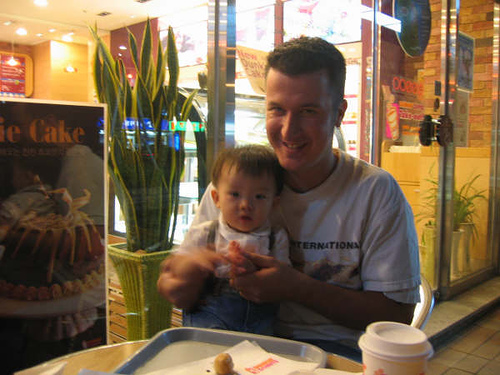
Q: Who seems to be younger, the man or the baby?
A: The baby is younger than the man.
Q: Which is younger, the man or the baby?
A: The baby is younger than the man.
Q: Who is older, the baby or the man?
A: The man is older than the baby.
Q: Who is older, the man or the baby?
A: The man is older than the baby.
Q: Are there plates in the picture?
A: No, there are no plates.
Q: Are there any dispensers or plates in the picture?
A: No, there are no plates or dispensers.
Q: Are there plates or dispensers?
A: No, there are no plates or dispensers.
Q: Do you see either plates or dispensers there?
A: No, there are no plates or dispensers.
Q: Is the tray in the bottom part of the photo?
A: Yes, the tray is in the bottom of the image.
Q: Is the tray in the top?
A: No, the tray is in the bottom of the image.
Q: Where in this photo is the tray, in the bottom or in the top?
A: The tray is in the bottom of the image.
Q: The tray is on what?
A: The tray is on the table.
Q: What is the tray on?
A: The tray is on the table.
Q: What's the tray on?
A: The tray is on the table.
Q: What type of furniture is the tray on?
A: The tray is on the table.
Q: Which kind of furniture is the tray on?
A: The tray is on the table.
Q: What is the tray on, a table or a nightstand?
A: The tray is on a table.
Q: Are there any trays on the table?
A: Yes, there is a tray on the table.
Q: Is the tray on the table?
A: Yes, the tray is on the table.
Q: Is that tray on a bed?
A: No, the tray is on the table.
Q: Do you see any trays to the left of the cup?
A: Yes, there is a tray to the left of the cup.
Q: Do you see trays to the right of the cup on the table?
A: No, the tray is to the left of the cup.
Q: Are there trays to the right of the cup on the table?
A: No, the tray is to the left of the cup.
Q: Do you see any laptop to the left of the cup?
A: No, there is a tray to the left of the cup.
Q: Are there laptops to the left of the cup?
A: No, there is a tray to the left of the cup.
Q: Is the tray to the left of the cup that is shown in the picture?
A: Yes, the tray is to the left of the cup.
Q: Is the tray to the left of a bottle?
A: No, the tray is to the left of the cup.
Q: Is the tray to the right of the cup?
A: No, the tray is to the left of the cup.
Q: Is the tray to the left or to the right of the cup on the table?
A: The tray is to the left of the cup.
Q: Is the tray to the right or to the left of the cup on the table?
A: The tray is to the left of the cup.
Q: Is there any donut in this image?
A: Yes, there is a donut.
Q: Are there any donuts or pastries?
A: Yes, there is a donut.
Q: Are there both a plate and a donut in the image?
A: No, there is a donut but no plates.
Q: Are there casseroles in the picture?
A: No, there are no casseroles.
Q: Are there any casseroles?
A: No, there are no casseroles.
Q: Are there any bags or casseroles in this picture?
A: No, there are no casseroles or bags.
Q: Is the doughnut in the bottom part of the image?
A: Yes, the doughnut is in the bottom of the image.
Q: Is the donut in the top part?
A: No, the donut is in the bottom of the image.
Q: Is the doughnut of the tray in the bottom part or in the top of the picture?
A: The doughnut is in the bottom of the image.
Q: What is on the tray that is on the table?
A: The donut is on the tray.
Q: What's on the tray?
A: The donut is on the tray.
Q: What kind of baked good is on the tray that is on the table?
A: The food is a donut.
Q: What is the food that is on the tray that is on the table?
A: The food is a donut.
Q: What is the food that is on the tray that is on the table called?
A: The food is a donut.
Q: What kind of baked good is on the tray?
A: The food is a donut.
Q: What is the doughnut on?
A: The doughnut is on the tray.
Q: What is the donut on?
A: The doughnut is on the tray.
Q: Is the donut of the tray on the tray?
A: Yes, the donut is on the tray.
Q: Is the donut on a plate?
A: No, the donut is on the tray.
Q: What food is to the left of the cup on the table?
A: The food is a donut.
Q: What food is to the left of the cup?
A: The food is a donut.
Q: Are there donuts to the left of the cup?
A: Yes, there is a donut to the left of the cup.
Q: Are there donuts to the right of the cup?
A: No, the donut is to the left of the cup.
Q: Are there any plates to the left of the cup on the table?
A: No, there is a donut to the left of the cup.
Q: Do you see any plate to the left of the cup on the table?
A: No, there is a donut to the left of the cup.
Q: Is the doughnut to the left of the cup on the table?
A: Yes, the doughnut is to the left of the cup.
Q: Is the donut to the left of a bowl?
A: No, the donut is to the left of the cup.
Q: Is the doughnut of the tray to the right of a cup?
A: No, the doughnut is to the left of a cup.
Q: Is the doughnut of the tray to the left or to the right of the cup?
A: The doughnut is to the left of the cup.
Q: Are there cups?
A: Yes, there is a cup.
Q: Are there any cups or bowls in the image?
A: Yes, there is a cup.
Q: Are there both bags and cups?
A: No, there is a cup but no bags.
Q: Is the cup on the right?
A: Yes, the cup is on the right of the image.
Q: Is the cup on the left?
A: No, the cup is on the right of the image.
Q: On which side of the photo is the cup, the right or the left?
A: The cup is on the right of the image.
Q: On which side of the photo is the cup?
A: The cup is on the right of the image.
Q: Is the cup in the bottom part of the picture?
A: Yes, the cup is in the bottom of the image.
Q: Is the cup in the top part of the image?
A: No, the cup is in the bottom of the image.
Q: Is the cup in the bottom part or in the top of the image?
A: The cup is in the bottom of the image.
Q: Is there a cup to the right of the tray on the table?
A: Yes, there is a cup to the right of the tray.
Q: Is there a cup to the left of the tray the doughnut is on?
A: No, the cup is to the right of the tray.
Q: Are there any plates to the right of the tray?
A: No, there is a cup to the right of the tray.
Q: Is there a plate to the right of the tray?
A: No, there is a cup to the right of the tray.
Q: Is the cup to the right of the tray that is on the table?
A: Yes, the cup is to the right of the tray.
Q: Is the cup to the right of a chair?
A: No, the cup is to the right of the tray.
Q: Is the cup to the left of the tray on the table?
A: No, the cup is to the right of the tray.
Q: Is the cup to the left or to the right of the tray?
A: The cup is to the right of the tray.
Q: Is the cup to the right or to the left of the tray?
A: The cup is to the right of the tray.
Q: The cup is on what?
A: The cup is on the table.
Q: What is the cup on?
A: The cup is on the table.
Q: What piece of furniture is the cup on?
A: The cup is on the table.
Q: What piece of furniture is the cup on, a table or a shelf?
A: The cup is on a table.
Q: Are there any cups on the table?
A: Yes, there is a cup on the table.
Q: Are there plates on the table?
A: No, there is a cup on the table.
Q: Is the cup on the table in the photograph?
A: Yes, the cup is on the table.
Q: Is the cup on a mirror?
A: No, the cup is on the table.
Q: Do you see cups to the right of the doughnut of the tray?
A: Yes, there is a cup to the right of the doughnut.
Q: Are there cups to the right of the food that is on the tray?
A: Yes, there is a cup to the right of the doughnut.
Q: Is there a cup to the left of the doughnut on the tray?
A: No, the cup is to the right of the doughnut.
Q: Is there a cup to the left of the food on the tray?
A: No, the cup is to the right of the doughnut.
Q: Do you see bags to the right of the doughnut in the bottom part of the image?
A: No, there is a cup to the right of the doughnut.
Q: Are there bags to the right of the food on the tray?
A: No, there is a cup to the right of the doughnut.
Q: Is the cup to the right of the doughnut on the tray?
A: Yes, the cup is to the right of the doughnut.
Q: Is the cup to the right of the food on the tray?
A: Yes, the cup is to the right of the doughnut.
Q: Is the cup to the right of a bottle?
A: No, the cup is to the right of the doughnut.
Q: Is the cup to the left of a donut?
A: No, the cup is to the right of a donut.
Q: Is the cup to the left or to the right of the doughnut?
A: The cup is to the right of the doughnut.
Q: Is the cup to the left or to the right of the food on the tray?
A: The cup is to the right of the doughnut.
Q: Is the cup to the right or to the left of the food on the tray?
A: The cup is to the right of the doughnut.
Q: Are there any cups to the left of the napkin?
A: No, the cup is to the right of the napkin.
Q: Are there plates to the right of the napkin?
A: No, there is a cup to the right of the napkin.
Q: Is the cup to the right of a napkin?
A: Yes, the cup is to the right of a napkin.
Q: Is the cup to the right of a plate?
A: No, the cup is to the right of a napkin.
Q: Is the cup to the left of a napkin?
A: No, the cup is to the right of a napkin.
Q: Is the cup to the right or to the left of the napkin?
A: The cup is to the right of the napkin.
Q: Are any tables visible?
A: Yes, there is a table.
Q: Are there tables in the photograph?
A: Yes, there is a table.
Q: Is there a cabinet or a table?
A: Yes, there is a table.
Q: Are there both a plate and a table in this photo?
A: No, there is a table but no plates.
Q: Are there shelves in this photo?
A: No, there are no shelves.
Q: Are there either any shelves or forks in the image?
A: No, there are no shelves or forks.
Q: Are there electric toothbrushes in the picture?
A: No, there are no electric toothbrushes.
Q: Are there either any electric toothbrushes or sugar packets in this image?
A: No, there are no electric toothbrushes or sugar packets.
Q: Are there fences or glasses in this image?
A: No, there are no glasses or fences.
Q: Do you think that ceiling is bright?
A: Yes, the ceiling is bright.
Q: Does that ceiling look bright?
A: Yes, the ceiling is bright.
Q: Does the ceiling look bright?
A: Yes, the ceiling is bright.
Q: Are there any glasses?
A: No, there are no glasses.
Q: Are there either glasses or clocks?
A: No, there are no glasses or clocks.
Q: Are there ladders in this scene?
A: No, there are no ladders.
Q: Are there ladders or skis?
A: No, there are no ladders or skis.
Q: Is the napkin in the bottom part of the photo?
A: Yes, the napkin is in the bottom of the image.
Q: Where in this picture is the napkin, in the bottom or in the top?
A: The napkin is in the bottom of the image.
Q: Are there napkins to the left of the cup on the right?
A: Yes, there is a napkin to the left of the cup.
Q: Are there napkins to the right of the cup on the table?
A: No, the napkin is to the left of the cup.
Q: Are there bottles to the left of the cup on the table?
A: No, there is a napkin to the left of the cup.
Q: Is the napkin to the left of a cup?
A: Yes, the napkin is to the left of a cup.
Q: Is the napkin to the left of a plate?
A: No, the napkin is to the left of a cup.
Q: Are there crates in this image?
A: No, there are no crates.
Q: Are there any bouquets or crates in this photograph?
A: No, there are no crates or bouquets.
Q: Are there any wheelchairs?
A: No, there are no wheelchairs.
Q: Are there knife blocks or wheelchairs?
A: No, there are no wheelchairs or knife blocks.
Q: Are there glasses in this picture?
A: No, there are no glasses.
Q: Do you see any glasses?
A: No, there are no glasses.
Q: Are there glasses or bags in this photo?
A: No, there are no glasses or bags.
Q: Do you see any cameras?
A: Yes, there is a camera.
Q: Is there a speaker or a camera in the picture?
A: Yes, there is a camera.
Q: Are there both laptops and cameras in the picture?
A: No, there is a camera but no laptops.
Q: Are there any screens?
A: No, there are no screens.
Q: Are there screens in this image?
A: No, there are no screens.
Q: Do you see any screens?
A: No, there are no screens.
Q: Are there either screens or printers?
A: No, there are no screens or printers.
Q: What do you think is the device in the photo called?
A: The device is a camera.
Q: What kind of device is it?
A: The device is a camera.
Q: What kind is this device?
A: This is a camera.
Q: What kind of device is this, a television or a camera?
A: This is a camera.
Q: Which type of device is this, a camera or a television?
A: This is a camera.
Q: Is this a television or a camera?
A: This is a camera.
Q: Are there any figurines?
A: No, there are no figurines.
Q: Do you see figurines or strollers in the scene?
A: No, there are no figurines or strollers.